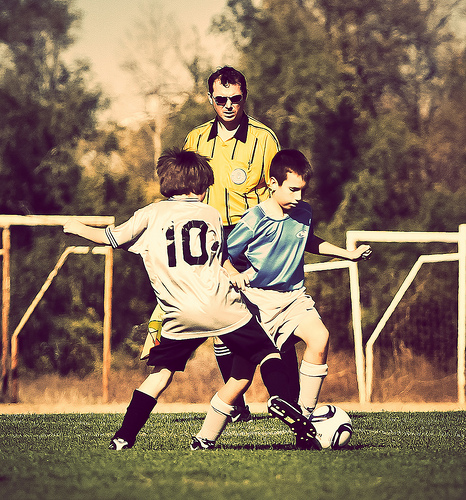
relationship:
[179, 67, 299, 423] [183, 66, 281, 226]
man wearing shirt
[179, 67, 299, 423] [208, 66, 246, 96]
man has hair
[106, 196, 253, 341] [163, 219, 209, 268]
shirt has number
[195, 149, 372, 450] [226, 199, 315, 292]
boy wearing shirt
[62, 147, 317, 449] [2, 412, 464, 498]
kids on grass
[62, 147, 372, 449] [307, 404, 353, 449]
kids kicking ball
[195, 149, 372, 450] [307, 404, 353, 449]
boy kicking ball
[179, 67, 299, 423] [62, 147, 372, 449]
man watching kids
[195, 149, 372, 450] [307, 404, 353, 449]
boy looking at ball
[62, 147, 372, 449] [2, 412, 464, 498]
kids on grass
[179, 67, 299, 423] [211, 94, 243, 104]
man has sunglasses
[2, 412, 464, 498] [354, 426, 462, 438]
grass has line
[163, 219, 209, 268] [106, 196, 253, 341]
number on shirt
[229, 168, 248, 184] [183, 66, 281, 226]
logo on shirt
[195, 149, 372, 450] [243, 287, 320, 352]
boy wearing shorts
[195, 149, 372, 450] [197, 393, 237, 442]
boy wearing socks